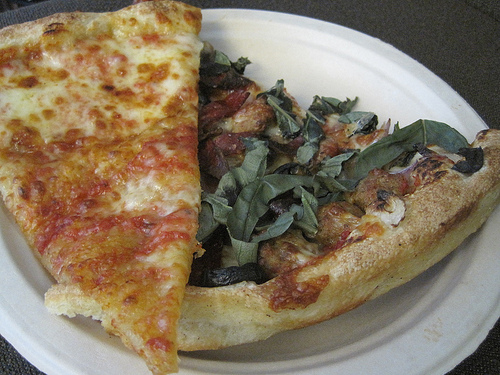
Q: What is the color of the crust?
A: Tan.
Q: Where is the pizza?
A: The plate.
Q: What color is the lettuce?
A: Green.